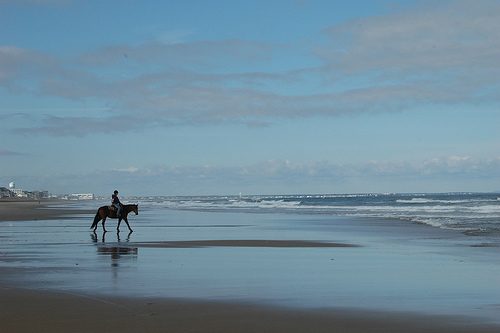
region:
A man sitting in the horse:
[75, 190, 175, 236]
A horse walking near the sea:
[70, 201, 180, 236]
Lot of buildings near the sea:
[1, 171, 471, 196]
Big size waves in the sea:
[191, 197, 481, 223]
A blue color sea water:
[311, 190, 391, 202]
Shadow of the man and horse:
[92, 241, 162, 271]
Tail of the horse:
[85, 210, 100, 230]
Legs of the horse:
[95, 220, 150, 240]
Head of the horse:
[130, 195, 150, 220]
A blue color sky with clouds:
[63, 10, 446, 154]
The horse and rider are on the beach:
[32, 118, 293, 288]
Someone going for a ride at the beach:
[55, 132, 421, 282]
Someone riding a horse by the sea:
[61, 143, 309, 284]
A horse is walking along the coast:
[66, 150, 243, 280]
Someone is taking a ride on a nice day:
[51, 85, 431, 273]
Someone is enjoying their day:
[51, 127, 309, 299]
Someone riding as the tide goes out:
[36, 85, 381, 277]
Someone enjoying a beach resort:
[55, 126, 450, 293]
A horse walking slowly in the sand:
[65, 157, 341, 288]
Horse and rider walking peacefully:
[70, 134, 445, 281]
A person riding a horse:
[88, 188, 145, 237]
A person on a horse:
[87, 190, 141, 235]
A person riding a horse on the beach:
[88, 185, 139, 235]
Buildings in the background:
[0, 181, 95, 203]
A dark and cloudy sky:
[3, 35, 496, 130]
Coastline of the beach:
[140, 193, 497, 239]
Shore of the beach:
[165, 225, 495, 332]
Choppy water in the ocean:
[158, 184, 498, 231]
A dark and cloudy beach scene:
[4, 6, 496, 329]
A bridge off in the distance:
[214, 189, 393, 201]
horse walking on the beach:
[87, 195, 139, 237]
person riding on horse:
[91, 188, 140, 237]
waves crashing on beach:
[144, 197, 494, 233]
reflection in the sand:
[94, 238, 139, 265]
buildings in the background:
[0, 180, 106, 200]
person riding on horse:
[111, 191, 126, 214]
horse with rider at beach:
[92, 205, 139, 230]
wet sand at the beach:
[38, 199, 490, 321]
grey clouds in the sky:
[8, 28, 495, 105]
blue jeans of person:
[112, 203, 123, 220]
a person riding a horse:
[67, 177, 141, 259]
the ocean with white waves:
[186, 179, 490, 243]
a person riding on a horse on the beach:
[89, 172, 171, 260]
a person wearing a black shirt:
[105, 184, 124, 212]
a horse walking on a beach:
[88, 192, 195, 259]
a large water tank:
[6, 169, 16, 196]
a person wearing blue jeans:
[105, 184, 125, 219]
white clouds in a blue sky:
[201, 26, 446, 148]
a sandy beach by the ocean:
[161, 194, 444, 329]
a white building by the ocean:
[63, 186, 99, 211]